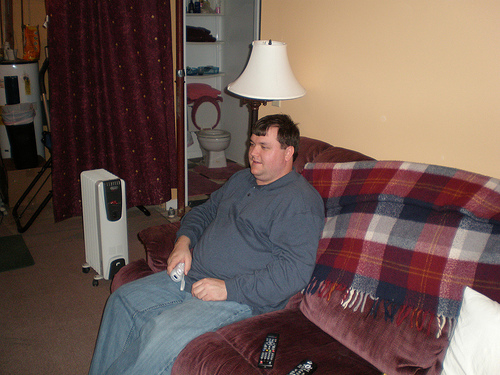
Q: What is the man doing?
A: Sitting on a couch.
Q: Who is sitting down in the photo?
A: A man.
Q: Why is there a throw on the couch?
A: To cover up with when cold.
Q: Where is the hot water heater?
A: In the back on the left.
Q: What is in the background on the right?
A: A toilet.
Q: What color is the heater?
A: White and black.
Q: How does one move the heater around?
A: With casters.